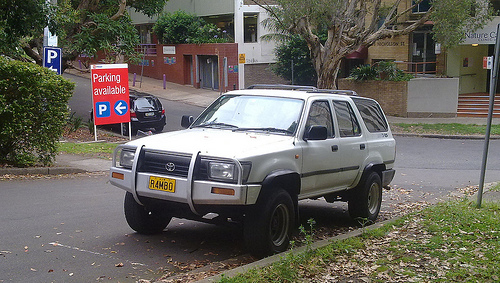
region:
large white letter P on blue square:
[95, 102, 107, 117]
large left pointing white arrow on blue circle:
[112, 96, 129, 118]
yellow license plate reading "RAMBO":
[148, 174, 175, 193]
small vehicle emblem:
[162, 159, 177, 171]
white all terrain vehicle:
[108, 63, 397, 252]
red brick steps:
[461, 92, 496, 117]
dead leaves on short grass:
[318, 233, 492, 275]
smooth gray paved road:
[10, 181, 104, 212]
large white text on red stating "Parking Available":
[90, 61, 125, 105]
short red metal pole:
[155, 72, 170, 91]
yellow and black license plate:
[145, 169, 179, 196]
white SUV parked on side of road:
[142, 76, 402, 236]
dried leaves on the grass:
[331, 240, 367, 280]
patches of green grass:
[424, 212, 496, 269]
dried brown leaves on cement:
[91, 232, 218, 281]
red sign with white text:
[91, 62, 132, 138]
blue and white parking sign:
[38, 46, 63, 77]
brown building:
[143, 33, 245, 91]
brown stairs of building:
[458, 85, 498, 129]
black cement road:
[10, 180, 123, 237]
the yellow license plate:
[147, 175, 176, 192]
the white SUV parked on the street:
[112, 84, 396, 243]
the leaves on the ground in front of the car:
[158, 250, 238, 279]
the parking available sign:
[89, 60, 135, 140]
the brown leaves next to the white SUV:
[335, 224, 487, 281]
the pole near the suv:
[475, 27, 498, 207]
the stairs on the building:
[458, 82, 490, 116]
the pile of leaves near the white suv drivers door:
[349, 237, 426, 278]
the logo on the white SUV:
[162, 160, 175, 173]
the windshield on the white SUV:
[202, 92, 303, 134]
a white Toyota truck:
[109, 74, 389, 246]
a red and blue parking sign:
[83, 59, 136, 136]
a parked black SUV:
[102, 86, 167, 134]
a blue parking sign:
[42, 43, 62, 77]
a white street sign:
[439, 11, 499, 214]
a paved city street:
[0, 149, 464, 274]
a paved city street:
[34, 61, 491, 181]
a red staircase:
[451, 91, 498, 117]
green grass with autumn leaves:
[249, 191, 499, 279]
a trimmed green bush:
[0, 51, 70, 167]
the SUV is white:
[99, 78, 420, 253]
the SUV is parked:
[90, 80, 408, 252]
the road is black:
[42, 180, 107, 231]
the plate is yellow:
[143, 172, 182, 196]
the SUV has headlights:
[100, 82, 418, 236]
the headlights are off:
[116, 145, 241, 187]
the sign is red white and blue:
[83, 57, 133, 136]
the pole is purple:
[159, 68, 170, 91]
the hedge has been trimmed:
[5, 57, 75, 158]